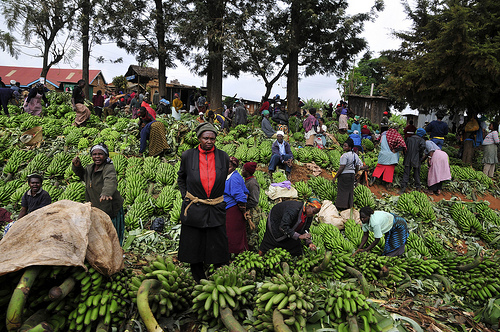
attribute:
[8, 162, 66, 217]
boy — standing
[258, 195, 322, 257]
lady — bending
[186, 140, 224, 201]
top — orange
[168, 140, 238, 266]
jacket — black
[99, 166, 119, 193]
arm — extended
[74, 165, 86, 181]
arm — extended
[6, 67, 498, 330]
bananas — green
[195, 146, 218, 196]
shirt — orange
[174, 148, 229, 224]
jacket — black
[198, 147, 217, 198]
shirt — red